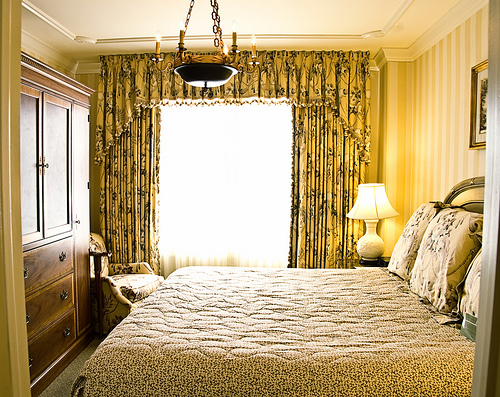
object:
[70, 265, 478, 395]
comfertor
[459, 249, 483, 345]
pillows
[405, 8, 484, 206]
wall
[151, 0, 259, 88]
lamp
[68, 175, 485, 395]
bed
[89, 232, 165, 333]
chair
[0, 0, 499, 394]
room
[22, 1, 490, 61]
crown molding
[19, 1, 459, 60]
ceiling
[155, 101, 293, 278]
window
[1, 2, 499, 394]
bedroom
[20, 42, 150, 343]
corner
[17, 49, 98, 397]
cabinet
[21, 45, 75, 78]
wall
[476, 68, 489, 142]
picture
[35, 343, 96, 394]
rug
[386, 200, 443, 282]
pillow cases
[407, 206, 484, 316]
pillows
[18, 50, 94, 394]
dresser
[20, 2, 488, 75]
molding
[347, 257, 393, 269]
table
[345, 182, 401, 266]
lamp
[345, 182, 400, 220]
lamp shade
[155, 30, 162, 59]
lights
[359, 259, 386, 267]
stand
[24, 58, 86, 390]
chest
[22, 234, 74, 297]
drawers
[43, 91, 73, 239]
door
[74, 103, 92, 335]
door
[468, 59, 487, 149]
frame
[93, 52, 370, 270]
curtains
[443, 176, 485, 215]
headboard